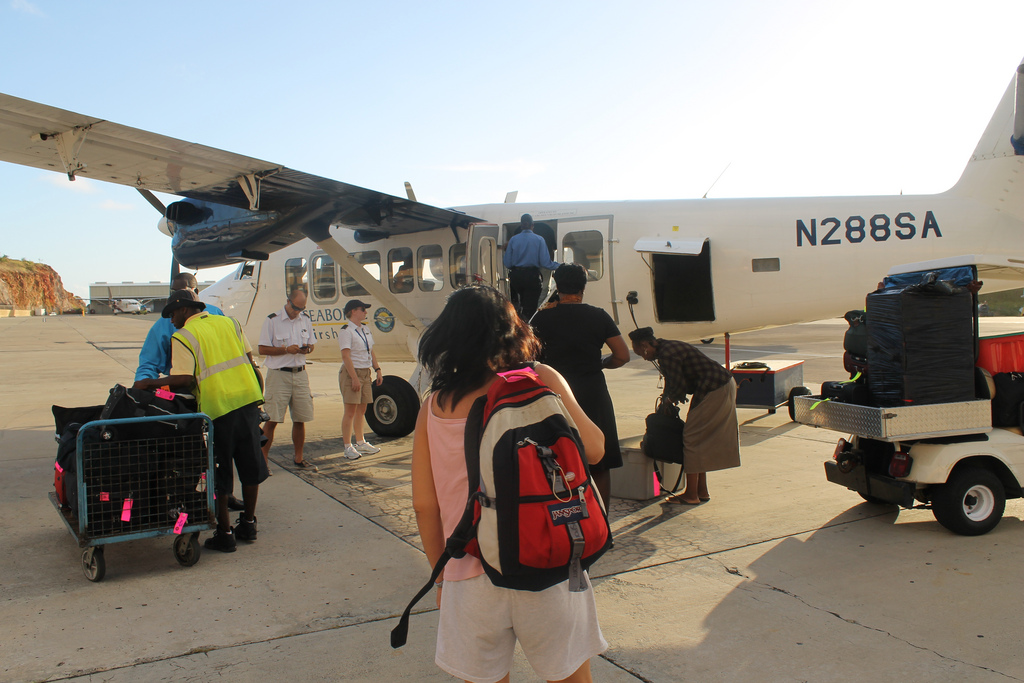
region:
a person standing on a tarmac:
[377, 264, 635, 672]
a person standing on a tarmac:
[537, 266, 637, 491]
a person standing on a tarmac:
[321, 294, 392, 453]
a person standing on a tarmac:
[258, 270, 326, 474]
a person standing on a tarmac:
[164, 279, 291, 562]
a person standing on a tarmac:
[113, 276, 180, 388]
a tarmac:
[9, 304, 1018, 677]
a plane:
[11, 77, 1020, 435]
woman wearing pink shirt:
[410, 288, 611, 681]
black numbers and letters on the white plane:
[784, 202, 944, 248]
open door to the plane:
[467, 219, 559, 356]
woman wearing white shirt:
[332, 292, 381, 460]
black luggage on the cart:
[50, 380, 210, 537]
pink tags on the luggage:
[47, 363, 199, 541]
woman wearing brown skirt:
[631, 316, 743, 506]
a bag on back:
[413, 342, 652, 565]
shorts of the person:
[435, 524, 639, 667]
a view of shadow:
[746, 528, 880, 664]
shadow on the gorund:
[698, 549, 896, 680]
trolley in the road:
[59, 372, 274, 594]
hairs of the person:
[401, 304, 516, 377]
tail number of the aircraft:
[792, 207, 947, 246]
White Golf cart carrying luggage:
[826, 257, 1017, 524]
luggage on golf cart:
[839, 269, 979, 405]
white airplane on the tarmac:
[5, 86, 1017, 409]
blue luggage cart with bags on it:
[49, 374, 215, 565]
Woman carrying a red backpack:
[408, 285, 608, 674]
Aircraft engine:
[131, 168, 348, 258]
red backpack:
[465, 367, 602, 577]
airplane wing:
[4, 84, 453, 268]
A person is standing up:
[133, 270, 223, 392]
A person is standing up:
[161, 292, 269, 552]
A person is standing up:
[255, 280, 316, 473]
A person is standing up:
[337, 298, 385, 455]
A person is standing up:
[528, 261, 628, 525]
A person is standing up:
[506, 213, 560, 319]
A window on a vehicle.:
[309, 254, 339, 300]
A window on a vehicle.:
[341, 250, 381, 298]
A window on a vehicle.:
[386, 245, 412, 291]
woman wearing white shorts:
[378, 288, 622, 681]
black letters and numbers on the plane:
[789, 202, 945, 251]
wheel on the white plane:
[347, 368, 423, 436]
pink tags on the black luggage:
[44, 377, 203, 534]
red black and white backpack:
[416, 357, 607, 582]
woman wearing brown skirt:
[620, 316, 751, 517]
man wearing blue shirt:
[499, 213, 558, 319]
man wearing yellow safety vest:
[157, 286, 272, 544]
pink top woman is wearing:
[413, 389, 506, 561]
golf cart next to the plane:
[789, 260, 1023, 524]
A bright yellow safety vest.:
[172, 311, 281, 426]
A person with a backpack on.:
[390, 272, 634, 671]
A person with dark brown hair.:
[399, 291, 628, 665]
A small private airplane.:
[8, 80, 1012, 419]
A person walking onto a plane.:
[476, 212, 562, 320]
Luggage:
[34, 370, 218, 548]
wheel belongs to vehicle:
[931, 456, 1008, 539]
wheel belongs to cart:
[80, 547, 106, 585]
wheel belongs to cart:
[170, 528, 200, 568]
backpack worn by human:
[380, 364, 608, 650]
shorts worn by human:
[426, 564, 607, 679]